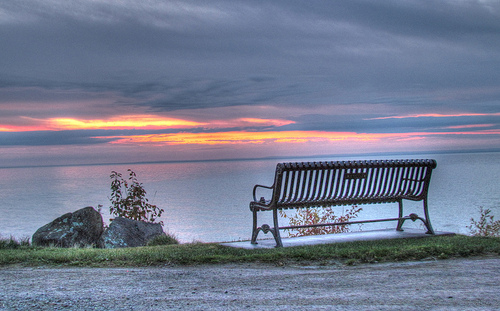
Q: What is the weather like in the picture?
A: It is overcast.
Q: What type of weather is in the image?
A: It is overcast.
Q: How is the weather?
A: It is overcast.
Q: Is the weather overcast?
A: Yes, it is overcast.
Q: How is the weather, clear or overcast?
A: It is overcast.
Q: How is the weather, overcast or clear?
A: It is overcast.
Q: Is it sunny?
A: No, it is overcast.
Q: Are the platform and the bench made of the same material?
A: No, the platform is made of concrete and the bench is made of metal.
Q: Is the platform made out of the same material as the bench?
A: No, the platform is made of concrete and the bench is made of metal.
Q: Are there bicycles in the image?
A: No, there are no bicycles.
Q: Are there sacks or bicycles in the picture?
A: No, there are no bicycles or sacks.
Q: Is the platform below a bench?
A: Yes, the platform is below a bench.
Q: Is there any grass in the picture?
A: Yes, there is grass.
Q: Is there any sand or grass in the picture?
A: Yes, there is grass.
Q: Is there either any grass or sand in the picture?
A: Yes, there is grass.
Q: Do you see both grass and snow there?
A: No, there is grass but no snow.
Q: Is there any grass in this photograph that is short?
A: Yes, there is short grass.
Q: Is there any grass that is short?
A: Yes, there is grass that is short.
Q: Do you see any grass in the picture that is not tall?
A: Yes, there is short grass.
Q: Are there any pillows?
A: No, there are no pillows.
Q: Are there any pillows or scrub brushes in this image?
A: No, there are no pillows or scrub brushes.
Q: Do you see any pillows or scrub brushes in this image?
A: No, there are no pillows or scrub brushes.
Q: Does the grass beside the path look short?
A: Yes, the grass is short.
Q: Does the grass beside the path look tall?
A: No, the grass is short.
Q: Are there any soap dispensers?
A: No, there are no soap dispensers.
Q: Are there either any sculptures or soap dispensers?
A: No, there are no soap dispensers or sculptures.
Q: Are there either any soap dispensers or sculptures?
A: No, there are no soap dispensers or sculptures.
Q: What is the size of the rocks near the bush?
A: The rocks are large.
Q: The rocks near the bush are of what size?
A: The rocks are large.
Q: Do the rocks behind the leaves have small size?
A: No, the rocks are large.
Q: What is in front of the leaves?
A: The rocks are in front of the leaves.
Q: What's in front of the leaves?
A: The rocks are in front of the leaves.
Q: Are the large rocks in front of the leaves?
A: Yes, the rocks are in front of the leaves.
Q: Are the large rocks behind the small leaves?
A: Yes, the rocks are behind the leaves.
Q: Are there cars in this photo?
A: No, there are no cars.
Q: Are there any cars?
A: No, there are no cars.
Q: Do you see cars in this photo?
A: No, there are no cars.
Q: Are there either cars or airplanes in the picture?
A: No, there are no cars or airplanes.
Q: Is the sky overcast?
A: Yes, the sky is overcast.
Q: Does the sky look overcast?
A: Yes, the sky is overcast.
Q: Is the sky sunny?
A: No, the sky is overcast.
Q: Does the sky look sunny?
A: No, the sky is overcast.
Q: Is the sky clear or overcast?
A: The sky is overcast.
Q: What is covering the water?
A: The sky is covering the water.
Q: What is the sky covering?
A: The sky is covering the water.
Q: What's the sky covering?
A: The sky is covering the water.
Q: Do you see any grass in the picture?
A: Yes, there is grass.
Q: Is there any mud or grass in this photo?
A: Yes, there is grass.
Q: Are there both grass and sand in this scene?
A: No, there is grass but no sand.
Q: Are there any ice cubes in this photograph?
A: No, there are no ice cubes.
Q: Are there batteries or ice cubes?
A: No, there are no ice cubes or batteries.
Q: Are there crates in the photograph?
A: No, there are no crates.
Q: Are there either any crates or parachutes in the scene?
A: No, there are no crates or parachutes.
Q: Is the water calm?
A: Yes, the water is calm.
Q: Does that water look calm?
A: Yes, the water is calm.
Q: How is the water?
A: The water is calm.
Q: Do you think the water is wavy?
A: No, the water is calm.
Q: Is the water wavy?
A: No, the water is calm.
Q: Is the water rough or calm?
A: The water is calm.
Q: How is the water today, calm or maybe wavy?
A: The water is calm.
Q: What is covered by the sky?
A: The water is covered by the sky.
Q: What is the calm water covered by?
A: The water is covered by the sky.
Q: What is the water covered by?
A: The water is covered by the sky.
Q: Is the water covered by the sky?
A: Yes, the water is covered by the sky.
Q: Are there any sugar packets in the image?
A: No, there are no sugar packets.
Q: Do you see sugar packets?
A: No, there are no sugar packets.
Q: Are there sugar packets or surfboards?
A: No, there are no sugar packets or surfboards.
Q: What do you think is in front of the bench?
A: The shrub is in front of the bench.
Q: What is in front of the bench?
A: The shrub is in front of the bench.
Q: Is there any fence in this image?
A: No, there are no fences.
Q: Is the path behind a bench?
A: Yes, the path is behind a bench.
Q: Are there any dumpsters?
A: No, there are no dumpsters.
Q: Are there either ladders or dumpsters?
A: No, there are no dumpsters or ladders.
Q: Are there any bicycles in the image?
A: No, there are no bicycles.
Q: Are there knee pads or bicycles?
A: No, there are no bicycles or knee pads.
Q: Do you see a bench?
A: Yes, there is a bench.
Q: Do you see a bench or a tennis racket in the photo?
A: Yes, there is a bench.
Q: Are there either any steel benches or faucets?
A: Yes, there is a steel bench.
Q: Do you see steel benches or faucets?
A: Yes, there is a steel bench.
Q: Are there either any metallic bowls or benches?
A: Yes, there is a metal bench.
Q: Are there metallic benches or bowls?
A: Yes, there is a metal bench.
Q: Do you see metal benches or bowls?
A: Yes, there is a metal bench.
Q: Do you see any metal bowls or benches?
A: Yes, there is a metal bench.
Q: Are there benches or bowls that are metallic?
A: Yes, the bench is metallic.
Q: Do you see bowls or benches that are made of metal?
A: Yes, the bench is made of metal.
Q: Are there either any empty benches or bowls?
A: Yes, there is an empty bench.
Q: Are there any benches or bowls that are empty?
A: Yes, the bench is empty.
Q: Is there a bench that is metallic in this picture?
A: Yes, there is a metal bench.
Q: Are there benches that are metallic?
A: Yes, there is a bench that is metallic.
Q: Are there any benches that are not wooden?
A: Yes, there is a metallic bench.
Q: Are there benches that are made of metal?
A: Yes, there is a bench that is made of metal.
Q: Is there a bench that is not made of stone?
A: Yes, there is a bench that is made of metal.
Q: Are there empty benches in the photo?
A: Yes, there is an empty bench.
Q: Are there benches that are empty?
A: Yes, there is a bench that is empty.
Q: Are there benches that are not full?
A: Yes, there is a empty bench.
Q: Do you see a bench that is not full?
A: Yes, there is a empty bench.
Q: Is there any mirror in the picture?
A: No, there are no mirrors.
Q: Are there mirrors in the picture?
A: No, there are no mirrors.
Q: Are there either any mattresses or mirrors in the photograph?
A: No, there are no mirrors or mattresses.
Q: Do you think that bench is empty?
A: Yes, the bench is empty.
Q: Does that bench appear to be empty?
A: Yes, the bench is empty.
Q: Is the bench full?
A: No, the bench is empty.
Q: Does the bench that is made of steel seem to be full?
A: No, the bench is empty.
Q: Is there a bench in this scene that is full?
A: No, there is a bench but it is empty.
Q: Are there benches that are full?
A: No, there is a bench but it is empty.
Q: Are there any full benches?
A: No, there is a bench but it is empty.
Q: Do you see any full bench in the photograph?
A: No, there is a bench but it is empty.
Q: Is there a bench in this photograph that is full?
A: No, there is a bench but it is empty.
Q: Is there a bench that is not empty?
A: No, there is a bench but it is empty.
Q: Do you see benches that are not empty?
A: No, there is a bench but it is empty.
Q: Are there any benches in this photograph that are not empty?
A: No, there is a bench but it is empty.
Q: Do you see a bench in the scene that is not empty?
A: No, there is a bench but it is empty.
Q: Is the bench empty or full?
A: The bench is empty.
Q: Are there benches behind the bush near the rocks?
A: Yes, there is a bench behind the bush.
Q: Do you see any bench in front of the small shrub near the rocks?
A: No, the bench is behind the bush.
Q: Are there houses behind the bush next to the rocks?
A: No, there is a bench behind the shrub.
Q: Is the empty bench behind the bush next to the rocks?
A: Yes, the bench is behind the shrub.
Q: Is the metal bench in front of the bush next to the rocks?
A: No, the bench is behind the shrub.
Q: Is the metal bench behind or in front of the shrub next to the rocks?
A: The bench is behind the bush.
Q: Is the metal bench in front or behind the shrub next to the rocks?
A: The bench is behind the bush.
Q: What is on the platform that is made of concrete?
A: The bench is on the platform.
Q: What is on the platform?
A: The bench is on the platform.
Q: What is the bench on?
A: The bench is on the platform.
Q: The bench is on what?
A: The bench is on the platform.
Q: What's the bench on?
A: The bench is on the platform.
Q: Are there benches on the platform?
A: Yes, there is a bench on the platform.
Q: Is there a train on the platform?
A: No, there is a bench on the platform.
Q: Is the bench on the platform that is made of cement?
A: Yes, the bench is on the platform.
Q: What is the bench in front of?
A: The bench is in front of the path.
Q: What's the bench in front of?
A: The bench is in front of the path.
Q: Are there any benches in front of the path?
A: Yes, there is a bench in front of the path.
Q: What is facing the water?
A: The bench is facing the water.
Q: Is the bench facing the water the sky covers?
A: Yes, the bench is facing the water.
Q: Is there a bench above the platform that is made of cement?
A: Yes, there is a bench above the platform.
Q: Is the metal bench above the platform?
A: Yes, the bench is above the platform.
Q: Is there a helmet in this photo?
A: No, there are no helmets.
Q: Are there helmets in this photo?
A: No, there are no helmets.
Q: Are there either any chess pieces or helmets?
A: No, there are no helmets or chess pieces.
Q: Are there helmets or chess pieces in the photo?
A: No, there are no helmets or chess pieces.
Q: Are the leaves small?
A: Yes, the leaves are small.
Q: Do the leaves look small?
A: Yes, the leaves are small.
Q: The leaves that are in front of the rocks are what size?
A: The leaves are small.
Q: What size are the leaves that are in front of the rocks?
A: The leaves are small.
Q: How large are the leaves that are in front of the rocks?
A: The leaves are small.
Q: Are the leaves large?
A: No, the leaves are small.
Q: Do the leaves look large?
A: No, the leaves are small.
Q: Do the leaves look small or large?
A: The leaves are small.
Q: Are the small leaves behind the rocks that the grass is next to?
A: Yes, the leaves are behind the rocks.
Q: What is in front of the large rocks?
A: The leaves are in front of the rocks.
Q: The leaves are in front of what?
A: The leaves are in front of the rocks.